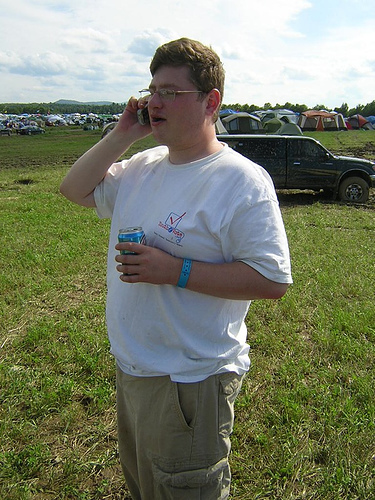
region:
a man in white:
[131, 119, 216, 482]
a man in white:
[144, 192, 252, 492]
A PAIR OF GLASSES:
[131, 83, 218, 103]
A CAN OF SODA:
[115, 223, 154, 285]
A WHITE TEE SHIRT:
[92, 143, 296, 385]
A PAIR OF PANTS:
[100, 359, 266, 496]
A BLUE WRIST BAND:
[170, 251, 205, 294]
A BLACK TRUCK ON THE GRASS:
[205, 127, 374, 203]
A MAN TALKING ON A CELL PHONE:
[60, 27, 308, 316]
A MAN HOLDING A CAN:
[51, 27, 321, 314]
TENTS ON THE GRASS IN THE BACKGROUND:
[221, 104, 374, 138]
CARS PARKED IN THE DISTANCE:
[4, 107, 108, 138]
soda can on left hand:
[111, 226, 152, 281]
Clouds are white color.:
[29, 31, 86, 80]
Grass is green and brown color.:
[271, 348, 353, 477]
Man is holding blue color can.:
[110, 218, 159, 282]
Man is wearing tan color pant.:
[123, 379, 207, 484]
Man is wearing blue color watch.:
[169, 256, 195, 289]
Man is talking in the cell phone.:
[107, 85, 187, 164]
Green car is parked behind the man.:
[231, 127, 367, 205]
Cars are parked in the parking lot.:
[7, 110, 112, 131]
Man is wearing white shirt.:
[87, 158, 223, 363]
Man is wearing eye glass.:
[139, 83, 206, 104]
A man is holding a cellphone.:
[92, 36, 230, 161]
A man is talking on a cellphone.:
[114, 31, 231, 167]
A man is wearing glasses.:
[117, 59, 233, 121]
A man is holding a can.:
[92, 218, 156, 297]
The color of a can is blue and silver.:
[98, 214, 163, 295]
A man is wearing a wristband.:
[171, 249, 196, 300]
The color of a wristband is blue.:
[168, 249, 195, 296]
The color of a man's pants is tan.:
[99, 345, 260, 499]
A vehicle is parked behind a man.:
[198, 122, 373, 216]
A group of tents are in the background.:
[0, 90, 374, 149]